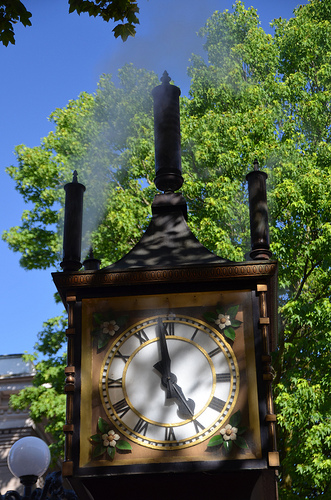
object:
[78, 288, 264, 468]
clock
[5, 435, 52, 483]
bulb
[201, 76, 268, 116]
leaves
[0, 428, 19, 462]
light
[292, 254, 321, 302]
branch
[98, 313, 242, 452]
watch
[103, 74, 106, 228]
steam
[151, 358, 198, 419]
minute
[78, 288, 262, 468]
on clock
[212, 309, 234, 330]
flowers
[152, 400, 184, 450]
middle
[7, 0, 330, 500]
tree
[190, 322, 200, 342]
one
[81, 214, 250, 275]
placed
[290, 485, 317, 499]
yard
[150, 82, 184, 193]
pole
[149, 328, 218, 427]
telling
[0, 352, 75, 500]
building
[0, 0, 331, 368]
sky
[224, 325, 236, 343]
leaf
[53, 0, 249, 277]
smoke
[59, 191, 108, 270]
venting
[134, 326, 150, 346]
time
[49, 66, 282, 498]
wooden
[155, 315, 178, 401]
hands